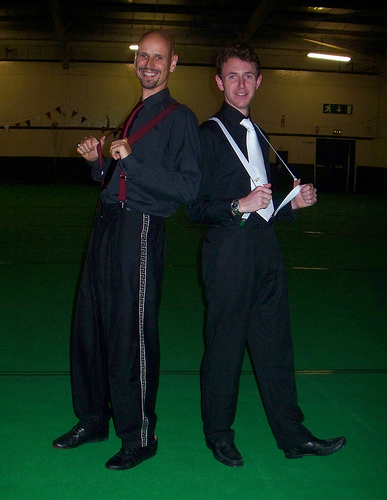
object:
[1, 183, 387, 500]
floor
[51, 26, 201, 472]
man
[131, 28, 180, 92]
head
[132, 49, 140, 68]
ear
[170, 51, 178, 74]
ear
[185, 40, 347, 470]
man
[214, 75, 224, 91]
ear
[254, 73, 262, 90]
ear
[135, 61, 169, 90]
facial hair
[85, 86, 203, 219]
shirt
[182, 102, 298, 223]
shirt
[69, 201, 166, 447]
dress pants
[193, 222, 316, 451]
dress pants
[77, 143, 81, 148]
ring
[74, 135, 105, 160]
right hand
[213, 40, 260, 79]
hair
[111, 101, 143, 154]
tie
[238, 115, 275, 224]
tie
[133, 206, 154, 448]
stripe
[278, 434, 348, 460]
shoe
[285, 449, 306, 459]
heel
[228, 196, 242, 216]
watch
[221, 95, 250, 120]
neck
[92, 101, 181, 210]
suspenders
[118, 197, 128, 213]
buckles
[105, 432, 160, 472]
shoe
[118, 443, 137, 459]
laces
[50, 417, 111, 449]
shoe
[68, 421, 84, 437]
laces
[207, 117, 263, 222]
suspenders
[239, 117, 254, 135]
knot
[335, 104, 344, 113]
sign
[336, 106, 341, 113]
arrow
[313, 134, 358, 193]
door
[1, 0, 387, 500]
room